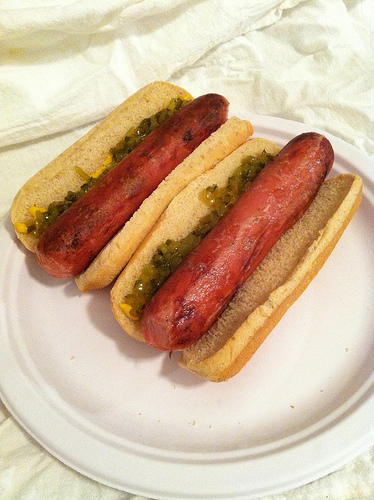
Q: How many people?
A: None.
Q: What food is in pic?
A: Hot dogs.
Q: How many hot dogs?
A: Two.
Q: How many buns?
A: Two.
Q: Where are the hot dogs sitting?
A: On a plate.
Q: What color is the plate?
A: White.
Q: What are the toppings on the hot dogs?
A: Mustard and relish.